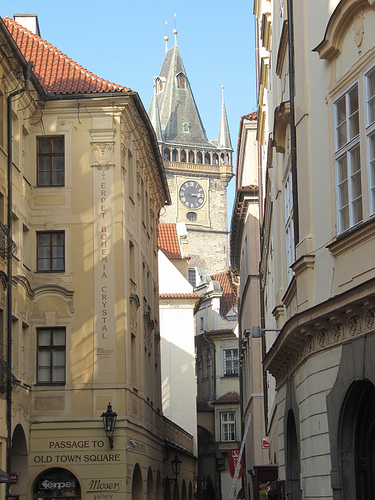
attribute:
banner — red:
[228, 443, 245, 479]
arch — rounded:
[129, 461, 144, 496]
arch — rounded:
[31, 463, 82, 498]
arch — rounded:
[145, 465, 156, 499]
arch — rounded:
[156, 469, 162, 497]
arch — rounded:
[163, 473, 173, 498]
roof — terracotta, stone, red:
[3, 15, 140, 95]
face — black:
[179, 180, 204, 209]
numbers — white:
[177, 175, 206, 209]